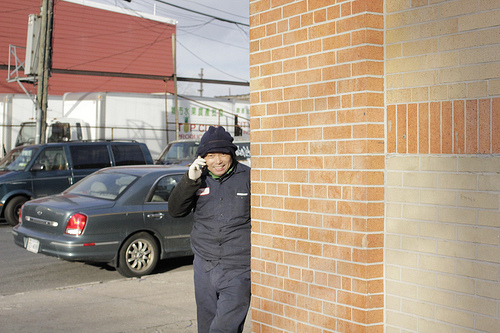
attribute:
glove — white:
[190, 159, 206, 184]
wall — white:
[53, 88, 195, 138]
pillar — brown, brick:
[248, 0, 385, 332]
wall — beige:
[386, 2, 498, 331]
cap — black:
[182, 103, 272, 160]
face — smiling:
[208, 154, 233, 175]